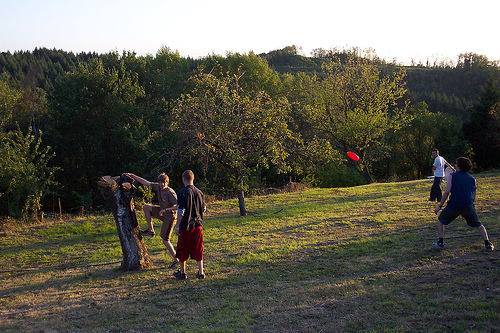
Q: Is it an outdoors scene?
A: Yes, it is outdoors.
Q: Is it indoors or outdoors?
A: It is outdoors.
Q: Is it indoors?
A: No, it is outdoors.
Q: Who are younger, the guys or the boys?
A: The boys are younger than the guys.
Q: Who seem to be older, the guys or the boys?
A: The guys are older than the boys.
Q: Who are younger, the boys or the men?
A: The boys are younger than the men.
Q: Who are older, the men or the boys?
A: The men are older than the boys.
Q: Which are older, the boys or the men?
A: The men are older than the boys.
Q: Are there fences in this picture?
A: No, there are no fences.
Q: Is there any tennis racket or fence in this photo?
A: No, there are no fences or rackets.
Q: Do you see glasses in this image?
A: No, there are no glasses.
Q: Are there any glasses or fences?
A: No, there are no glasses or fences.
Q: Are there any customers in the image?
A: No, there are no customers.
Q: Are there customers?
A: No, there are no customers.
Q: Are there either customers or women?
A: No, there are no customers or women.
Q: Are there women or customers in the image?
A: No, there are no customers or women.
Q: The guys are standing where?
A: The guys are standing on the field.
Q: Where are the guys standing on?
A: The guys are standing on the field.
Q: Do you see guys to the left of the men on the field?
A: Yes, there are guys to the left of the men.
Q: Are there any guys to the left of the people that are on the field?
A: Yes, there are guys to the left of the men.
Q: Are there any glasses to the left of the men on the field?
A: No, there are guys to the left of the men.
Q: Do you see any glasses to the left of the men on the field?
A: No, there are guys to the left of the men.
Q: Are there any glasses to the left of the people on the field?
A: No, there are guys to the left of the men.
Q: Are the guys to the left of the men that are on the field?
A: Yes, the guys are to the left of the men.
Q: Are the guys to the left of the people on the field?
A: Yes, the guys are to the left of the men.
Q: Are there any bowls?
A: No, there are no bowls.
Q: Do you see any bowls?
A: No, there are no bowls.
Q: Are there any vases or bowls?
A: No, there are no bowls or vases.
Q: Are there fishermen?
A: No, there are no fishermen.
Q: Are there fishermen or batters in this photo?
A: No, there are no fishermen or batters.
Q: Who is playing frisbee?
A: The men are playing frisbee.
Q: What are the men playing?
A: The men are playing frisbee.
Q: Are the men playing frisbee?
A: Yes, the men are playing frisbee.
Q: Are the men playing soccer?
A: No, the men are playing frisbee.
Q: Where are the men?
A: The men are on the field.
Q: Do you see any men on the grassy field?
A: Yes, there are men on the field.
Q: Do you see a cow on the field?
A: No, there are men on the field.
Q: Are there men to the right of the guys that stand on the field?
A: Yes, there are men to the right of the guys.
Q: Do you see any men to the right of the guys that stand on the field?
A: Yes, there are men to the right of the guys.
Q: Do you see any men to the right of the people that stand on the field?
A: Yes, there are men to the right of the guys.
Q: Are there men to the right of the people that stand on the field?
A: Yes, there are men to the right of the guys.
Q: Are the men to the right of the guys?
A: Yes, the men are to the right of the guys.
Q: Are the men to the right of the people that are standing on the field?
A: Yes, the men are to the right of the guys.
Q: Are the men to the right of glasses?
A: No, the men are to the right of the guys.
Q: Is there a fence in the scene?
A: No, there are no fences.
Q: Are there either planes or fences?
A: No, there are no fences or planes.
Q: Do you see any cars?
A: No, there are no cars.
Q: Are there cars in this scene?
A: No, there are no cars.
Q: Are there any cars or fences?
A: No, there are no cars or fences.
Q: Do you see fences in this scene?
A: No, there are no fences.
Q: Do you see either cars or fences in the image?
A: No, there are no fences or cars.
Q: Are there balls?
A: No, there are no balls.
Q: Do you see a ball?
A: No, there are no balls.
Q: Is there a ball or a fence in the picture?
A: No, there are no balls or fences.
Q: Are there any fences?
A: No, there are no fences.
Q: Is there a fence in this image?
A: No, there are no fences.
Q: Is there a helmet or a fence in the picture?
A: No, there are no fences or helmets.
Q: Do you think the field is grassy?
A: Yes, the field is grassy.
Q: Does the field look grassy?
A: Yes, the field is grassy.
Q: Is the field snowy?
A: No, the field is grassy.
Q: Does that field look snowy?
A: No, the field is grassy.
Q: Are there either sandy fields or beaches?
A: No, there is a field but it is grassy.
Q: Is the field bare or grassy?
A: The field is grassy.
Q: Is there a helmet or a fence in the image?
A: No, there are no fences or helmets.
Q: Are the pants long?
A: Yes, the pants are long.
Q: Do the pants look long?
A: Yes, the pants are long.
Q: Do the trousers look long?
A: Yes, the trousers are long.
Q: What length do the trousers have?
A: The trousers have long length.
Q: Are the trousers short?
A: No, the trousers are long.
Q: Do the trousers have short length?
A: No, the trousers are long.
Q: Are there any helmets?
A: No, there are no helmets.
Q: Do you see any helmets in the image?
A: No, there are no helmets.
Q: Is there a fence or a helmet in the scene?
A: No, there are no helmets or fences.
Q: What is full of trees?
A: The hill is full of trees.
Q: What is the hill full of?
A: The hill is full of trees.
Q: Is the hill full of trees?
A: Yes, the hill is full of trees.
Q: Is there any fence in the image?
A: No, there are no fences.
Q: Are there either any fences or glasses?
A: No, there are no fences or glasses.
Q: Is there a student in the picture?
A: No, there are no students.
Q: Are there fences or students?
A: No, there are no students or fences.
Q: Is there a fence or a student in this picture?
A: No, there are no students or fences.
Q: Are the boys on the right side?
A: Yes, the boys are on the right of the image.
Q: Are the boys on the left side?
A: No, the boys are on the right of the image.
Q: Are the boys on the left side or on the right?
A: The boys are on the right of the image.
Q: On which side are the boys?
A: The boys are on the right of the image.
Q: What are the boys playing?
A: The boys are playing frisbee.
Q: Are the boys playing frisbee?
A: Yes, the boys are playing frisbee.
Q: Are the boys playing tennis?
A: No, the boys are playing frisbee.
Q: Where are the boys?
A: The boys are in the field.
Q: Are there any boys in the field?
A: Yes, there are boys in the field.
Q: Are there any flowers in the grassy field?
A: No, there are boys in the field.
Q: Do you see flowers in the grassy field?
A: No, there are boys in the field.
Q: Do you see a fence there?
A: No, there are no fences.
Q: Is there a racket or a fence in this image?
A: No, there are no fences or rackets.